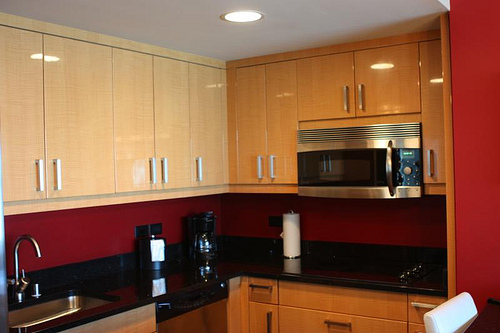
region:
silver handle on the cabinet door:
[194, 155, 204, 183]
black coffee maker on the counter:
[176, 208, 221, 265]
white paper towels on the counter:
[280, 205, 304, 260]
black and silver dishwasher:
[153, 273, 232, 331]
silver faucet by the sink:
[6, 232, 48, 301]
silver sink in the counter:
[5, 288, 115, 330]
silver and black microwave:
[293, 120, 425, 201]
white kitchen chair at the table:
[420, 290, 480, 331]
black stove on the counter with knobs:
[284, 245, 444, 288]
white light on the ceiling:
[219, 5, 267, 25]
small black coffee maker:
[178, 205, 227, 261]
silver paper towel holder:
[269, 204, 319, 263]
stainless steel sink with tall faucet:
[3, 234, 125, 329]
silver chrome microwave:
[293, 121, 426, 203]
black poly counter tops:
[236, 229, 458, 302]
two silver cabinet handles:
[249, 148, 281, 184]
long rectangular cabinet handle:
[188, 151, 208, 188]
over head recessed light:
[214, 6, 287, 31]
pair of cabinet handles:
[25, 148, 77, 200]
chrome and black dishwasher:
[155, 282, 242, 328]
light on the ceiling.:
[231, 8, 258, 24]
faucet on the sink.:
[24, 238, 39, 263]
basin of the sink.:
[24, 306, 80, 325]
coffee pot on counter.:
[191, 213, 213, 255]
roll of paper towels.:
[280, 215, 298, 259]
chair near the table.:
[440, 296, 464, 323]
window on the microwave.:
[320, 160, 377, 177]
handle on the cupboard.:
[357, 82, 363, 109]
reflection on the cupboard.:
[34, 50, 61, 67]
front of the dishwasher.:
[185, 305, 220, 321]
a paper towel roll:
[283, 210, 302, 257]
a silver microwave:
[298, 120, 421, 193]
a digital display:
[401, 149, 412, 156]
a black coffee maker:
[180, 210, 222, 264]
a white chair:
[423, 288, 477, 327]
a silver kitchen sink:
[3, 233, 121, 331]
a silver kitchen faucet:
[3, 233, 51, 293]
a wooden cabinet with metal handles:
[0, 30, 110, 206]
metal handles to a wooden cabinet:
[27, 156, 68, 192]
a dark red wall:
[452, 0, 498, 290]